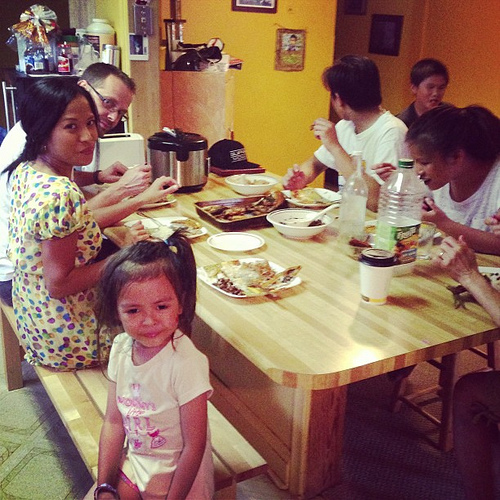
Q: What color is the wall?
A: Yellow.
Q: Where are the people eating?
A: At a table.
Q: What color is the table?
A: Wood.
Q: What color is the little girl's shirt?
A: White and pink.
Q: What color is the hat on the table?
A: Black and white.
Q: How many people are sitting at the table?
A: 6.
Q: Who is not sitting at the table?
A: The boy in the black shirt.